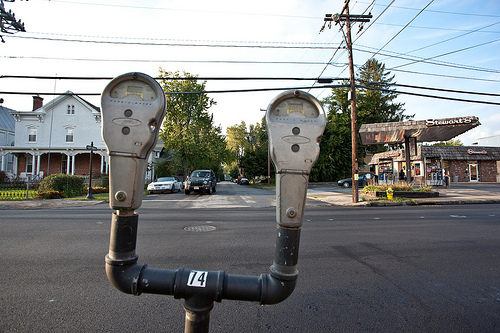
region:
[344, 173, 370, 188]
a car in front of the store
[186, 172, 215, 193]
a car driving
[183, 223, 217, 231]
a storm drain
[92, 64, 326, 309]
a parking meter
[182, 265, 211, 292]
a number on the parking meter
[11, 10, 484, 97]
wires in the sky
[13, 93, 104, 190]
a house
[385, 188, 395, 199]
a yellow fire hydrant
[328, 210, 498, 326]
pavement on the ground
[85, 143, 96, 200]
a street sign on the side of the road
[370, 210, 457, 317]
this is the road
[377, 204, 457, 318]
the road is tarmacked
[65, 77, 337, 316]
this is a hydrant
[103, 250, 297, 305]
this is a pipe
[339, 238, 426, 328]
the road is black in color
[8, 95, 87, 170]
this is the house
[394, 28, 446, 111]
these are electric lines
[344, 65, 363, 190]
this is a post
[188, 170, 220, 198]
the car is parked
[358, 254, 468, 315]
the road is tarmaced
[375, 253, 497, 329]
the road is rough and rugged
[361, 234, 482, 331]
the road is grey in color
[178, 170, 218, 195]
the car is black in color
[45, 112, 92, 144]
the roof is white in color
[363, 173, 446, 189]
the ground has green and yellow grassess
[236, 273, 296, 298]
the pipe is black in color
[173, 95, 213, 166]
the trees are green in color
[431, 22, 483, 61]
the sky is blue in color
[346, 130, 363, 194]
the electric post is metallic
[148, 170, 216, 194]
Vehicles on the street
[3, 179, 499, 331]
The street near the parking meters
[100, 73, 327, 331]
Parking meters near the street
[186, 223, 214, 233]
A sewer grate on the street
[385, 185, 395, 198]
A yellow hydrant near the grass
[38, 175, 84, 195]
A bush by the fence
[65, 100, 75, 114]
A window on the house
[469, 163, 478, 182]
A door at the gas station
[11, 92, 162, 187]
A house across from the gas station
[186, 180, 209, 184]
Headlights on the car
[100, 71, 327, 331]
two metal parking meters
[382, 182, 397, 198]
a yellow fire hydrant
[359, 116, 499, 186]
a brown gas station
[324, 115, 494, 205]
gas station on the corner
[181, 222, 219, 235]
manhole cover in the road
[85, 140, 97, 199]
a metal street sign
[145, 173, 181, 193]
a white convertible car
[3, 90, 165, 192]
white two story home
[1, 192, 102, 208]
side walk in front of a home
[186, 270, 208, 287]
white sticker with the number 74 on it